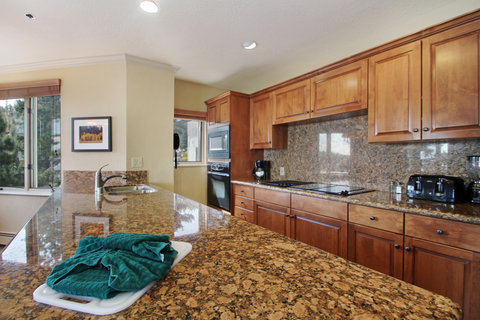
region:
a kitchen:
[5, 8, 478, 311]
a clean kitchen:
[1, 4, 477, 317]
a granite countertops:
[0, 170, 461, 318]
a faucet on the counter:
[92, 161, 126, 204]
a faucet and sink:
[91, 162, 160, 200]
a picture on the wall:
[66, 112, 114, 154]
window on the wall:
[0, 96, 58, 187]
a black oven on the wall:
[203, 160, 233, 211]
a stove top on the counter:
[287, 181, 380, 196]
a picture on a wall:
[84, 112, 119, 156]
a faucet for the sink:
[86, 155, 129, 197]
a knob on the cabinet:
[361, 207, 380, 234]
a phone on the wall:
[164, 126, 188, 153]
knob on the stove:
[338, 177, 353, 197]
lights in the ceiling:
[231, 28, 272, 60]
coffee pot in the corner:
[249, 155, 276, 179]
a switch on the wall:
[128, 153, 149, 174]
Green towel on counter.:
[61, 232, 166, 309]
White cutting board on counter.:
[42, 272, 102, 318]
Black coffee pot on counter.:
[253, 156, 277, 184]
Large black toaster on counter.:
[409, 172, 449, 201]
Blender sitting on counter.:
[463, 155, 479, 198]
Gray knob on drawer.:
[432, 225, 450, 236]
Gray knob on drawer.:
[356, 211, 377, 226]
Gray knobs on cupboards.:
[390, 238, 416, 259]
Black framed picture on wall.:
[68, 111, 127, 163]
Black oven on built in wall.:
[206, 158, 228, 207]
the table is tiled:
[200, 230, 290, 318]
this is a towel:
[50, 225, 167, 296]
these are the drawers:
[377, 46, 462, 131]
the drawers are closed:
[388, 48, 466, 132]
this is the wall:
[117, 65, 171, 105]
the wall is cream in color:
[138, 82, 169, 120]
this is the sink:
[316, 181, 355, 198]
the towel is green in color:
[55, 228, 169, 292]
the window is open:
[174, 117, 205, 157]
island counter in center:
[18, 174, 287, 317]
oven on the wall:
[206, 166, 230, 199]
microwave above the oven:
[209, 128, 233, 154]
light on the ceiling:
[239, 35, 269, 59]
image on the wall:
[64, 105, 116, 153]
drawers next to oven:
[230, 184, 250, 217]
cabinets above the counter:
[369, 44, 474, 143]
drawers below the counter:
[351, 203, 475, 242]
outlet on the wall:
[129, 153, 148, 168]